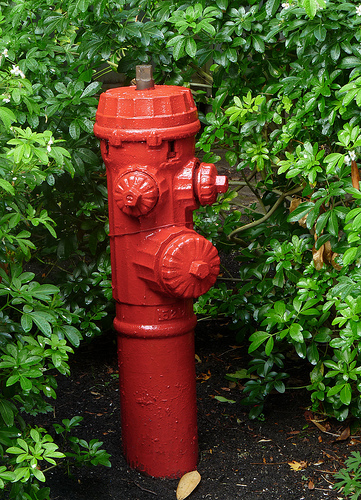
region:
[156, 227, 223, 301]
cover over fire hydrant port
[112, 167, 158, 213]
cover over fire hydrant port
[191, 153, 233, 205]
cover over fire hydrant port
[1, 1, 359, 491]
green bushes around fire hydrant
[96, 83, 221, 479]
bright red fire hydrant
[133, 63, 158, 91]
valve to turn on fire hydrant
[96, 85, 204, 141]
top of red fire hydrant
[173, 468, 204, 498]
brown leaf on ground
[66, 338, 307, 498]
dirt around fire hydrant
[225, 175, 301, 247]
stem of green bush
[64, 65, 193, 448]
the hydrant is red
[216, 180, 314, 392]
the leaves are wet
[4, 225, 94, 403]
the leaves are wet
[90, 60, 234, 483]
Red fire hydrant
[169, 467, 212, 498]
Fallen brown leaf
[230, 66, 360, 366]
Green bush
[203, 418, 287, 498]
Dark brown soil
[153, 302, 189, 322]
Numbers on a fire hydrant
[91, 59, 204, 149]
Top of a fire hydrant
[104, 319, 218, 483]
Base of a fire hydrant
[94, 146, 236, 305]
Middle of a fire hydrant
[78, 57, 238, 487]
A fire hydrant among bushes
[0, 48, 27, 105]
White flowers in a bush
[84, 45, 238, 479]
a fire hydrant color red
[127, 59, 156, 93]
a knob color gray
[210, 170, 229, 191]
a knob color red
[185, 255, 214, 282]
a knob color red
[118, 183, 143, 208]
a knob color red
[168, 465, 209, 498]
a dry leaf on ground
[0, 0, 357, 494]
leaves behind a fire hydrant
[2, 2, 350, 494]
green leaves behind a fire hydrant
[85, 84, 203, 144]
bonnet of fire hydrant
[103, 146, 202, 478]
barrel of fire hydrant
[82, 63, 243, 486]
this is a fire hydrant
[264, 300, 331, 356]
these are leaves on a branch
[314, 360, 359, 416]
these are leaves on a branch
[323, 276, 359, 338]
these are leaves on a branch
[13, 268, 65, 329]
these are leaves on a branch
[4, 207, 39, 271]
these are leaves on a branch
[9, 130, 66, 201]
these are leaves on a branch